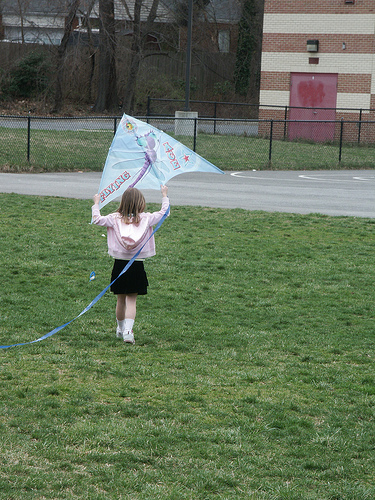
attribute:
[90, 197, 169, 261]
jacket — pink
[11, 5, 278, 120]
trees — bare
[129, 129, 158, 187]
dragonfly cartoon — purple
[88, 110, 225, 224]
kite — long, blue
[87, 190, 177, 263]
jacket — long-sleeved, pink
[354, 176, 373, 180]
circles — white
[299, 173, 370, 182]
circles — white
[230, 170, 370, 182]
circles — white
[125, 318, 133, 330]
sock — white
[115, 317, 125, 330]
sock — white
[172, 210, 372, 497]
grass — green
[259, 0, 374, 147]
building — red, white, brick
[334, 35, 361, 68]
building — brick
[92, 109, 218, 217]
kite — blue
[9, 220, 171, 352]
tail — long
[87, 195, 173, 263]
jacket — pink, hoody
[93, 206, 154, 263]
sweatshirt — pink, hooded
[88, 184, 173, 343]
girl — little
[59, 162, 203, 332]
girl — little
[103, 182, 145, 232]
hair — blonde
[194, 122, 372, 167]
fence — black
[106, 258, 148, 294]
skirt — high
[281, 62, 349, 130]
door — faded, red